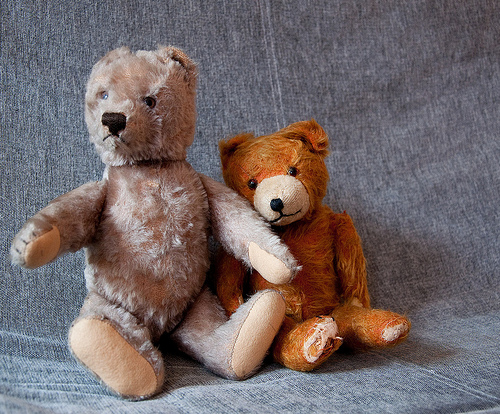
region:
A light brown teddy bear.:
[22, 41, 299, 398]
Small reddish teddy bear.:
[210, 76, 423, 387]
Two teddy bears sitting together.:
[5, 41, 440, 396]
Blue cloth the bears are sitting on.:
[360, 44, 479, 269]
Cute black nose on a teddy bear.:
[84, 97, 151, 152]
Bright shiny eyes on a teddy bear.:
[233, 141, 310, 208]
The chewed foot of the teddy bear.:
[283, 302, 359, 371]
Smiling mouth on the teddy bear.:
[236, 171, 322, 226]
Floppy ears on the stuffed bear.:
[197, 95, 336, 173]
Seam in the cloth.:
[211, 3, 310, 133]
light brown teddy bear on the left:
[10, 43, 294, 399]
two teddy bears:
[11, 43, 406, 393]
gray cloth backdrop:
[5, 5, 499, 412]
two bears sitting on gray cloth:
[13, 45, 409, 399]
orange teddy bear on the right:
[218, 120, 408, 369]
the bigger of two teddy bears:
[10, 48, 295, 397]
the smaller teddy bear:
[216, 118, 411, 370]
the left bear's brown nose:
[102, 113, 124, 132]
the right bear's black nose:
[270, 198, 281, 209]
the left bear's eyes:
[97, 92, 156, 108]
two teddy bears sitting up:
[49, 32, 413, 391]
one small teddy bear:
[212, 114, 413, 367]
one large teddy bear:
[33, 26, 275, 393]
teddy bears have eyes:
[80, 61, 320, 207]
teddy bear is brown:
[74, 52, 236, 360]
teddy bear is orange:
[215, 124, 397, 369]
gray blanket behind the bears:
[253, 25, 463, 107]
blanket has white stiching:
[250, 12, 305, 112]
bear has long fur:
[317, 235, 369, 294]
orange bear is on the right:
[219, 112, 415, 370]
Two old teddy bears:
[10, 43, 415, 395]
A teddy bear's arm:
[7, 180, 110, 270]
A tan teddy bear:
[6, 44, 302, 397]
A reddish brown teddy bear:
[216, 115, 413, 373]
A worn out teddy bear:
[217, 118, 418, 372]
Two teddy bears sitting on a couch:
[9, 25, 419, 402]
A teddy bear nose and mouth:
[92, 106, 149, 156]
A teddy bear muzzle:
[251, 175, 313, 225]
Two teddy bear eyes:
[238, 163, 301, 190]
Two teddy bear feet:
[67, 287, 287, 395]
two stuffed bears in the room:
[25, 30, 393, 290]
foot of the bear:
[355, 297, 410, 363]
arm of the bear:
[0, 181, 96, 281]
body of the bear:
[117, 185, 192, 275]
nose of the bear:
[247, 185, 300, 235]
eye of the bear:
[271, 152, 308, 189]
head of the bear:
[78, 39, 199, 164]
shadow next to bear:
[411, 333, 464, 390]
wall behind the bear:
[374, 65, 456, 137]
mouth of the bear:
[86, 130, 135, 158]